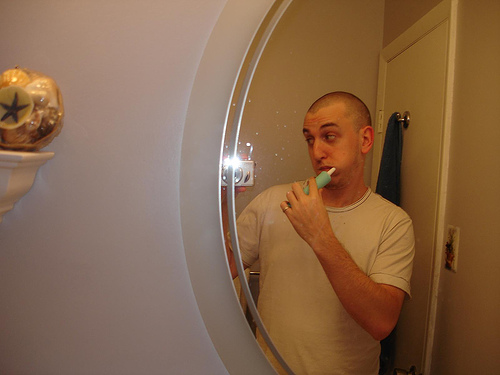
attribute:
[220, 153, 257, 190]
camera — silver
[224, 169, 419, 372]
shirt — white